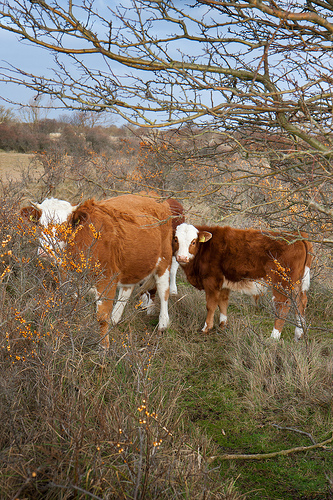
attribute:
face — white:
[171, 221, 211, 266]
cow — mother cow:
[19, 191, 174, 350]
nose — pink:
[176, 254, 195, 268]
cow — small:
[167, 216, 316, 339]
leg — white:
[112, 280, 140, 332]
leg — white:
[155, 256, 172, 331]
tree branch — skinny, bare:
[0, 12, 98, 53]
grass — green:
[174, 345, 330, 493]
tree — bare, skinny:
[0, 4, 331, 219]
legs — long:
[51, 255, 183, 355]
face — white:
[173, 219, 207, 267]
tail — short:
[299, 237, 311, 294]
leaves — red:
[2, 221, 101, 288]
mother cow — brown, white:
[23, 199, 188, 382]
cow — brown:
[27, 153, 303, 338]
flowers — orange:
[132, 156, 176, 187]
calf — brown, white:
[172, 219, 314, 337]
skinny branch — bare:
[212, 126, 331, 187]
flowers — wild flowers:
[23, 216, 105, 292]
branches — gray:
[154, 36, 271, 124]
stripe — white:
[170, 219, 200, 260]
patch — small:
[179, 372, 278, 457]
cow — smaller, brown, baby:
[173, 220, 313, 345]